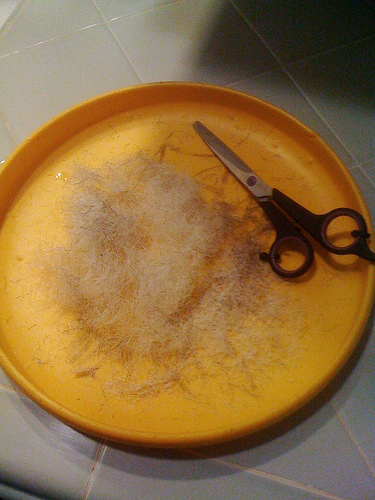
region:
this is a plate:
[140, 81, 191, 119]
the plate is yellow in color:
[124, 85, 181, 137]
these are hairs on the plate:
[91, 203, 213, 322]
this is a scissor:
[275, 202, 348, 270]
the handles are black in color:
[270, 198, 331, 253]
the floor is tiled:
[72, 17, 131, 74]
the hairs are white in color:
[66, 178, 213, 337]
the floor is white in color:
[74, 4, 164, 62]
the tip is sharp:
[189, 121, 223, 155]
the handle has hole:
[321, 215, 351, 243]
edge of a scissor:
[218, 136, 236, 157]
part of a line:
[250, 468, 276, 491]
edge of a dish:
[164, 426, 217, 461]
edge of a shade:
[196, 469, 227, 489]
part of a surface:
[315, 445, 351, 474]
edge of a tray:
[151, 417, 199, 452]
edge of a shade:
[64, 452, 95, 488]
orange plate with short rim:
[4, 68, 370, 466]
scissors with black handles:
[188, 115, 373, 288]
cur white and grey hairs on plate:
[6, 167, 263, 455]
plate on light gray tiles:
[41, 20, 312, 123]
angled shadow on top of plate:
[171, 4, 374, 123]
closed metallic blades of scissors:
[179, 100, 277, 214]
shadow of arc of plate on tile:
[9, 336, 370, 486]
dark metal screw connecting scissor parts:
[240, 163, 263, 196]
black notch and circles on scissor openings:
[254, 217, 374, 280]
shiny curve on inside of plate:
[216, 103, 342, 194]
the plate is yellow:
[198, 409, 207, 436]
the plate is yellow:
[183, 430, 195, 447]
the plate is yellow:
[185, 412, 191, 430]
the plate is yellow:
[175, 413, 187, 441]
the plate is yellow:
[169, 426, 181, 439]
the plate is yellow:
[181, 420, 197, 450]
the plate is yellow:
[180, 420, 190, 448]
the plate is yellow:
[183, 401, 198, 441]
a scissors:
[180, 79, 353, 327]